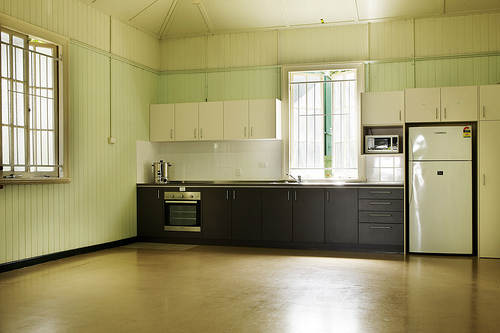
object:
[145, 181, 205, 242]
oven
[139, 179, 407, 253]
shelves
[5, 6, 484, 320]
kitchen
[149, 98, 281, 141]
cabinets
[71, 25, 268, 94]
wall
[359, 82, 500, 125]
cabinets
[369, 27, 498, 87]
wall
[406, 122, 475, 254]
fridge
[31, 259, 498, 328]
floor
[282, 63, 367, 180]
window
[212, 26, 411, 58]
wall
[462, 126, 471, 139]
magnet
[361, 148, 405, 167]
shelf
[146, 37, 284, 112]
wall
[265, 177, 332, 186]
sink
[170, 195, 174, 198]
knob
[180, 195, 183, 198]
knob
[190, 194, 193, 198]
knob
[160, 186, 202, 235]
stove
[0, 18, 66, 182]
window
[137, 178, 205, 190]
counter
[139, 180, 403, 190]
countertop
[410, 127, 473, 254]
door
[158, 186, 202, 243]
door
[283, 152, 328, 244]
handles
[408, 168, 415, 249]
handle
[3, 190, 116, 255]
wall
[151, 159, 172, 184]
appliance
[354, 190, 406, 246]
drawers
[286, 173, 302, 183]
faucet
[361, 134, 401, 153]
appliance